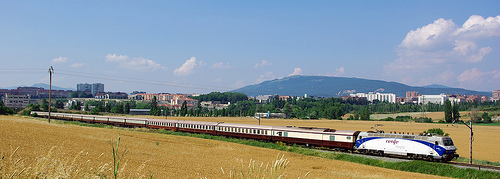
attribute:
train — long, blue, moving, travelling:
[76, 110, 466, 159]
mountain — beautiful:
[185, 16, 268, 53]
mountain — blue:
[256, 69, 352, 97]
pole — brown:
[44, 75, 56, 95]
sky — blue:
[290, 3, 366, 49]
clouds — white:
[408, 20, 469, 62]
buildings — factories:
[5, 88, 40, 111]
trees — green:
[304, 96, 350, 122]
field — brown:
[71, 135, 115, 170]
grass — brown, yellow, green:
[35, 128, 74, 163]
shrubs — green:
[225, 104, 248, 115]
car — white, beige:
[369, 129, 454, 164]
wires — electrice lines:
[51, 68, 84, 80]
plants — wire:
[254, 141, 283, 155]